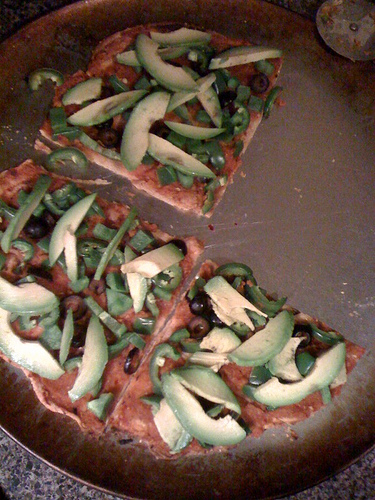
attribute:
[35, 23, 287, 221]
pizza — sliced, flatbread, saucy, brown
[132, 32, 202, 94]
avocado — cut up, sliced, green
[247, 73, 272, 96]
black olive — on pizza, sliced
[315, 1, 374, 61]
pizza cutter — covered in sauce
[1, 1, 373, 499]
pizza pan — brown, with empty space, sectioned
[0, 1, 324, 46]
table — marble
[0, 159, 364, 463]
pizza — half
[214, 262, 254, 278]
pepper — cut up, green